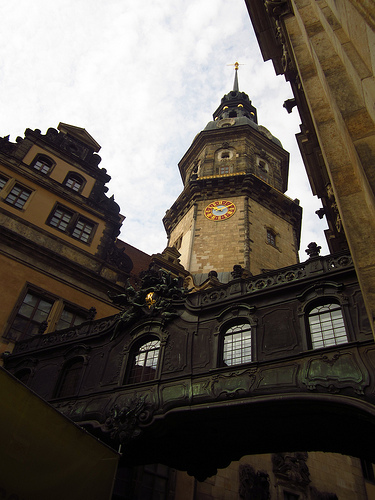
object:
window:
[59, 167, 89, 196]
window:
[7, 282, 60, 334]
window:
[301, 292, 351, 351]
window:
[47, 339, 107, 409]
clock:
[203, 200, 242, 223]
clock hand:
[208, 203, 220, 213]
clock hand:
[215, 201, 231, 213]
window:
[40, 182, 103, 246]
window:
[68, 213, 97, 246]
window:
[27, 151, 58, 175]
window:
[115, 328, 172, 381]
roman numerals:
[204, 200, 233, 221]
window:
[218, 315, 252, 367]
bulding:
[0, 0, 373, 498]